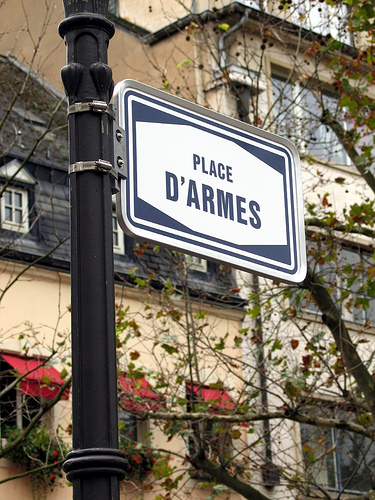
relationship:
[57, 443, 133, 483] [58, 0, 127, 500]
trim on pole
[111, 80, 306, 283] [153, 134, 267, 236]
sign saying place d'armes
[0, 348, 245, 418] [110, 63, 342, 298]
canopies behind sign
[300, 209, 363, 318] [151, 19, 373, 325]
window on building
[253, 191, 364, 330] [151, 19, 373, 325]
floor in building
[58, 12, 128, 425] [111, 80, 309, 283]
pole holding sign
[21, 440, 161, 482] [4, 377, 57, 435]
flower baskets under windows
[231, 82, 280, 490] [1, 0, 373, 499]
gutter on building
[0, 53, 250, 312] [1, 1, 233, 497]
roof of building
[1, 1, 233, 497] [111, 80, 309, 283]
building behind sign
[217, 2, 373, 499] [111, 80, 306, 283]
building next to sign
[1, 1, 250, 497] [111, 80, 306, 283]
building next to sign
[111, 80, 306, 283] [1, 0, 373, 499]
sign near building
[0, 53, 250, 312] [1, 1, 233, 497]
roof on a building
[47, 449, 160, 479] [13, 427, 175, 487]
red berries with leaves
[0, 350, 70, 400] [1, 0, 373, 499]
covering on building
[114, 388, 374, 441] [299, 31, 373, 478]
tree branch on tree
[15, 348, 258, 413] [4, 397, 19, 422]
canopies are over window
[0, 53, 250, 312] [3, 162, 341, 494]
roof on top of building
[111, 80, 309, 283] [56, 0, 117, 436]
sign attached to pole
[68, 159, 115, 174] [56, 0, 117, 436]
bracket attached to pole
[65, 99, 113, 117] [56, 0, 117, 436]
bracket attached to pole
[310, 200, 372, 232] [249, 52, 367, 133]
leeves are attached to tree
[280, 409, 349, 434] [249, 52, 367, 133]
branch attached to tree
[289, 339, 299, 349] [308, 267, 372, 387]
flowers are on plant